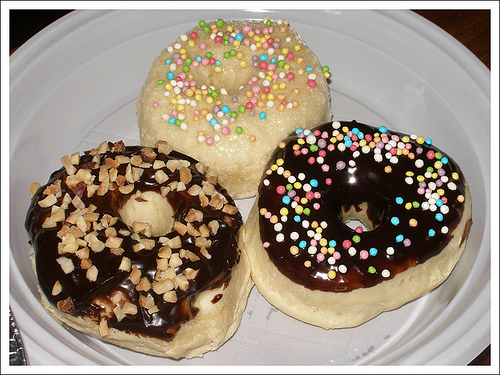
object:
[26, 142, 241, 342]
chocolate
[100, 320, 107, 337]
nuts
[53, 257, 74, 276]
peanuts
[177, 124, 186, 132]
sprinkles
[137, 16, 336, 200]
donut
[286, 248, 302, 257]
sprinkles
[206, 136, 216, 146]
glaze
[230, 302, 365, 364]
pattern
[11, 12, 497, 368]
bowl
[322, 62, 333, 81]
sprinkle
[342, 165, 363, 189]
light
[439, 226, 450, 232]
frosting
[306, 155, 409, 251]
chocolate frosting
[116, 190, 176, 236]
hole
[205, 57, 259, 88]
hole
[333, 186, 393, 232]
hole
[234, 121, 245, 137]
sprinkle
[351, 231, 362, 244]
sprinkle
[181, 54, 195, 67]
sprinkle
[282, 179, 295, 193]
sprinkle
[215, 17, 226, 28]
sprinkle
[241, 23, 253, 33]
sprinkle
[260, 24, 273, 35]
sprinkle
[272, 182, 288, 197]
sprinkle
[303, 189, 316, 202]
sprinkle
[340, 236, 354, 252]
sprinkle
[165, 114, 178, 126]
sprinkle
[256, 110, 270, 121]
sprinkle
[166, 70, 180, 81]
sprinkle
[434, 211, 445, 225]
sprinkle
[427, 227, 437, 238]
sprinkle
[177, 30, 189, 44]
sprinkle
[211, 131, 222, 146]
sprinkle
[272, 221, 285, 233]
sprinkle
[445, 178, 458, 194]
sprinkle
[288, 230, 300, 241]
sprinkle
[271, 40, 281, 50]
sprinkle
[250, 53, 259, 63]
sprinkle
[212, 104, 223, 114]
sprinkle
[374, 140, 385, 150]
sprinkle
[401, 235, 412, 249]
sprinkle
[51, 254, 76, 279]
nut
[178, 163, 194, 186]
nut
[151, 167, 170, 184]
nut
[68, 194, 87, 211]
nut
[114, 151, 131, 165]
nut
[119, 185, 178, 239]
middle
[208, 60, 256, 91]
middle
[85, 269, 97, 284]
walnuts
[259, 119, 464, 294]
chocolate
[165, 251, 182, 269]
walnut chunk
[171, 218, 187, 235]
walnut chunk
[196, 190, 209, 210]
walnut chunk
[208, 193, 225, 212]
walnut chunk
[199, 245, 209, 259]
walnut chunk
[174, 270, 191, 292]
walnut chunk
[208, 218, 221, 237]
walnut chunk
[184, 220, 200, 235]
walnut chunk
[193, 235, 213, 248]
walnut chunk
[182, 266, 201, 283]
walnut chunk